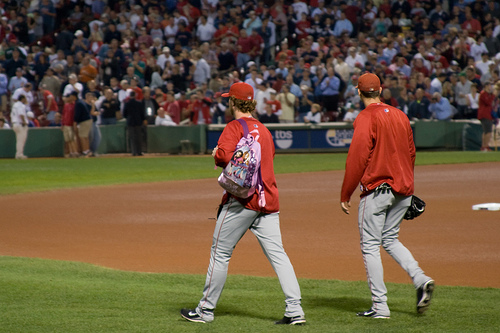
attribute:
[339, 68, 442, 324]
player — baseball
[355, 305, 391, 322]
shoe — Nike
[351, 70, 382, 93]
hat — Red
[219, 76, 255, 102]
cap — orange, baseball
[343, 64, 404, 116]
baseball cap — orange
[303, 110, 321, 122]
shirt — white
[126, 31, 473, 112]
fans — watching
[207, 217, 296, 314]
pants — gray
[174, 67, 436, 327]
uniforms — red, white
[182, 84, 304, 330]
player — baseball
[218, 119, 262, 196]
backpack — pink, purple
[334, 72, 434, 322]
player — baseball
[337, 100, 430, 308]
uniform — gray, red, baseball uniform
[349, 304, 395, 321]
shoe — Nike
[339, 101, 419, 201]
jacket — red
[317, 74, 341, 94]
shirt — blue